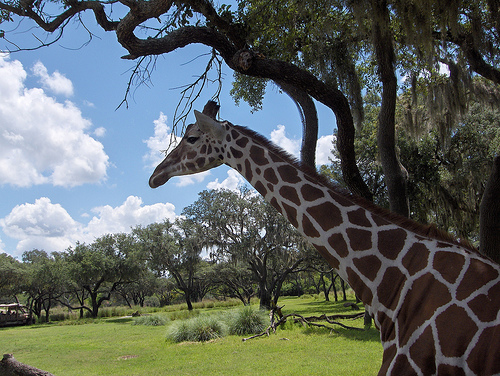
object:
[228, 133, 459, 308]
neck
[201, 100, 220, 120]
ear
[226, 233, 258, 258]
leaves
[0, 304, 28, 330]
car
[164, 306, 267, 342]
green leaves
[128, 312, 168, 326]
green leaves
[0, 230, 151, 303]
green leaves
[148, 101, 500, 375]
brown giraffe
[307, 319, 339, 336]
stick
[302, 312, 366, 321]
stick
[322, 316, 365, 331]
stick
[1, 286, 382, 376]
ground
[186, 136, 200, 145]
eye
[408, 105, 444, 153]
leaves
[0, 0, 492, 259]
sky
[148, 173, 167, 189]
mouth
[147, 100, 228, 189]
head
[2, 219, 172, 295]
leaves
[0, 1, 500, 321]
tree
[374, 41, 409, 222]
trunk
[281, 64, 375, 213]
trunk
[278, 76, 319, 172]
trunk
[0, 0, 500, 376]
field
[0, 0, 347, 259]
cloud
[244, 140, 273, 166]
spot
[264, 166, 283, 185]
spot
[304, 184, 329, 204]
spot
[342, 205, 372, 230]
spot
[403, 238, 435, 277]
spot